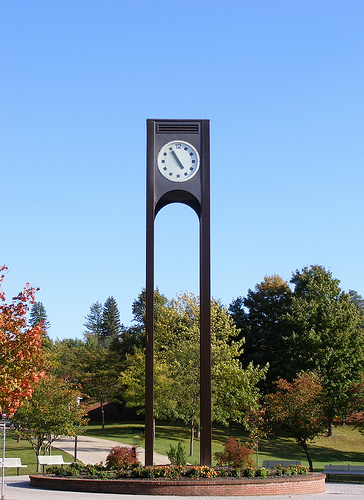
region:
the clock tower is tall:
[139, 116, 219, 465]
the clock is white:
[160, 142, 199, 178]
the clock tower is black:
[145, 116, 209, 465]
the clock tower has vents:
[140, 119, 212, 464]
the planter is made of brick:
[28, 471, 331, 498]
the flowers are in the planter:
[56, 465, 310, 474]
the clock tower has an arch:
[142, 116, 215, 467]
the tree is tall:
[278, 263, 363, 401]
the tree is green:
[288, 265, 362, 383]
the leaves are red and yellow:
[2, 266, 45, 410]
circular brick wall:
[27, 468, 328, 498]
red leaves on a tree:
[0, 266, 45, 418]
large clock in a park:
[143, 114, 213, 194]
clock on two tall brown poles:
[137, 113, 213, 470]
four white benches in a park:
[0, 453, 362, 480]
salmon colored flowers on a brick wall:
[132, 462, 219, 480]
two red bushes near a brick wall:
[108, 437, 252, 467]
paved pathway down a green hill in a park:
[30, 428, 192, 468]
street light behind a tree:
[67, 392, 85, 462]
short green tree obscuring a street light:
[11, 371, 86, 470]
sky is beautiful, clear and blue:
[3, 1, 361, 345]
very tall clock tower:
[144, 114, 213, 474]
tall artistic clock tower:
[144, 114, 219, 466]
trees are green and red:
[0, 260, 359, 497]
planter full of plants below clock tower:
[28, 445, 326, 497]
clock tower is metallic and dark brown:
[142, 110, 216, 477]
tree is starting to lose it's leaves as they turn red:
[1, 260, 49, 483]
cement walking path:
[33, 422, 192, 475]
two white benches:
[0, 449, 78, 477]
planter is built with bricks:
[27, 456, 326, 497]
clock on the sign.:
[156, 138, 202, 183]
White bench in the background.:
[36, 452, 72, 470]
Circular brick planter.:
[28, 467, 325, 496]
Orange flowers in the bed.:
[119, 461, 217, 475]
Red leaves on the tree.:
[0, 262, 46, 421]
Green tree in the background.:
[118, 285, 271, 456]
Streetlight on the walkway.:
[71, 393, 80, 460]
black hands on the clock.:
[157, 139, 199, 183]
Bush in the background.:
[107, 445, 137, 466]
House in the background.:
[68, 397, 139, 426]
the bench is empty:
[29, 448, 91, 477]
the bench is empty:
[2, 446, 38, 476]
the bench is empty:
[258, 447, 363, 485]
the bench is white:
[22, 442, 74, 468]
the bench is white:
[271, 454, 312, 479]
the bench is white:
[2, 445, 41, 479]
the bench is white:
[26, 443, 104, 483]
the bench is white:
[242, 444, 317, 485]